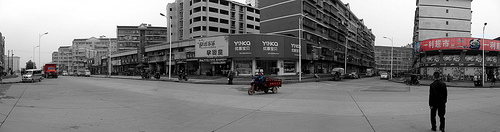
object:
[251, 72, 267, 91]
man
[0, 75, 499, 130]
street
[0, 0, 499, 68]
sky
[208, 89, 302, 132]
line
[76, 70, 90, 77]
cars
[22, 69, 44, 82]
automobile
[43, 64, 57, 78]
truck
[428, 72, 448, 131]
person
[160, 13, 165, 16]
light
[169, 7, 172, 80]
pole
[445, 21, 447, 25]
window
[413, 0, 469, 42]
building